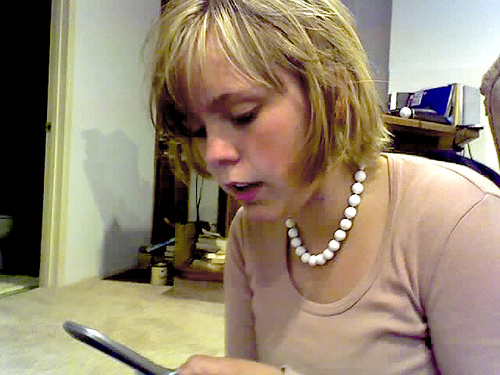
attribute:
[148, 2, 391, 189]
hair — short , blonde 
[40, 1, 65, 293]
frame — metal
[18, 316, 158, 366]
phone — mobile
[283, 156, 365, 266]
necklace — white, pearl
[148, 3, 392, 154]
hair — short, blonde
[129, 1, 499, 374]
girl — young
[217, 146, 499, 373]
shirt — pink 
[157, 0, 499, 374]
woman — young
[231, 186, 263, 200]
lip — Dark 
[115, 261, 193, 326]
rug — yellow, floor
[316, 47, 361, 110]
hair — messy, short, blonde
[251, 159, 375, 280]
necklace — White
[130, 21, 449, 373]
lady — looking 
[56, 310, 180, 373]
cell phone — silver 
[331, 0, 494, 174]
paint — white